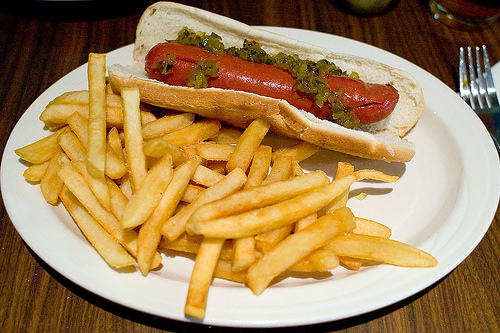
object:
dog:
[102, 8, 426, 133]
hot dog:
[142, 40, 403, 122]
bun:
[98, 1, 427, 166]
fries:
[83, 53, 108, 178]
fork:
[454, 38, 500, 115]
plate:
[6, 19, 499, 333]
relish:
[158, 23, 369, 125]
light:
[227, 65, 361, 102]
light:
[460, 76, 495, 96]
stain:
[461, 72, 468, 87]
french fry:
[176, 234, 225, 318]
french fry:
[338, 234, 440, 270]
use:
[16, 2, 439, 297]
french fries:
[244, 210, 360, 297]